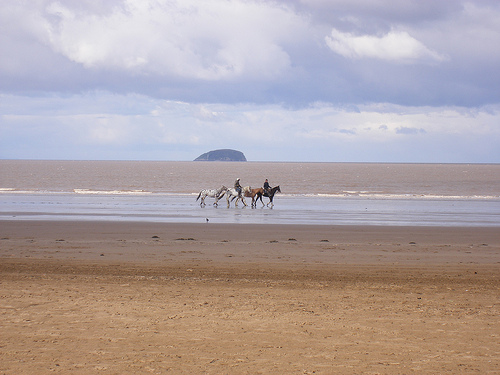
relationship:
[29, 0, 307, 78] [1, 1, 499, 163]
clouds in sky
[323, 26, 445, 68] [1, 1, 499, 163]
clouds in sky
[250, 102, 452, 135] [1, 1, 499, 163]
clouds in sky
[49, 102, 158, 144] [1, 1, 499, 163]
clouds in sky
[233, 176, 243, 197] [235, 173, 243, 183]
person wearing a hat